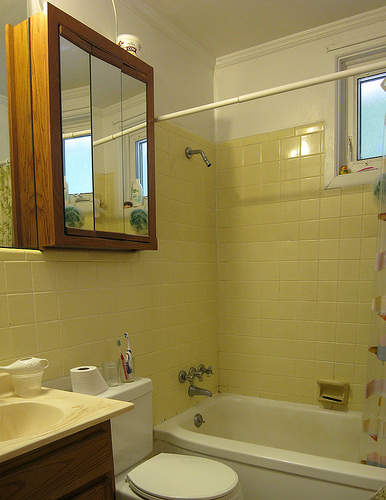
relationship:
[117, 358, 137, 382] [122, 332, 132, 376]
glass holding toothbrush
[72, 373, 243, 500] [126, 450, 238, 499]
toilet has lid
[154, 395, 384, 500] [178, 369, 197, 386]
bathtub has faucet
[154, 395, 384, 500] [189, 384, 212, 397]
bathtub has tap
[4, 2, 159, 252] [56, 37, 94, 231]
medicine cabinet has mirror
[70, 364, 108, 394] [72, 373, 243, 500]
toilet paper on back of toilet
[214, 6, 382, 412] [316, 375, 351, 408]
shower wall has soap holder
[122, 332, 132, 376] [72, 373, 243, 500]
toothbrush on back of toilet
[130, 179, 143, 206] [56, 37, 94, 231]
bottle reflected in mirror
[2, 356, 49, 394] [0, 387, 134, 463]
teapot on top of counter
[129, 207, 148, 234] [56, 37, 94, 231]
shower poof refelcted in mirror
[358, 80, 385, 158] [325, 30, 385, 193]
window has rim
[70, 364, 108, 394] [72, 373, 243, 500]
toilet paper on top of toilet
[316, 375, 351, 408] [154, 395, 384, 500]
soap holder on side of bathtub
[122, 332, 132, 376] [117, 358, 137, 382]
toothbrush sitting in glass